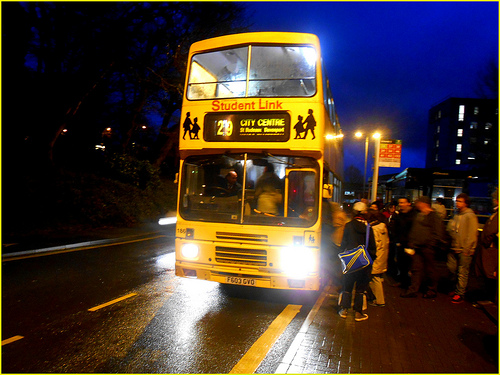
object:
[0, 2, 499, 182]
sky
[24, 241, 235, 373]
road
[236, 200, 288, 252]
ground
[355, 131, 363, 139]
lights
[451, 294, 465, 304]
shoe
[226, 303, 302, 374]
yellow line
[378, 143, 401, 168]
sign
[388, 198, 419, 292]
people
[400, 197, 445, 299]
man w/greenhat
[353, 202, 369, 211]
cap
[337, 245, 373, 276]
bag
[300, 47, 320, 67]
light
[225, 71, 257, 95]
light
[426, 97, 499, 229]
building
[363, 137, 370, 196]
lamp pole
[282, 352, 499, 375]
brick sidewalk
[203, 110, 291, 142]
sign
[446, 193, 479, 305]
people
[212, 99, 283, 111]
bus writing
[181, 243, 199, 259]
headlight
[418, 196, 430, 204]
hat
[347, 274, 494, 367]
sidewalk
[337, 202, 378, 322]
people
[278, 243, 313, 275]
headlights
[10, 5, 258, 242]
trees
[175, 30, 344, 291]
bus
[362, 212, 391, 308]
person